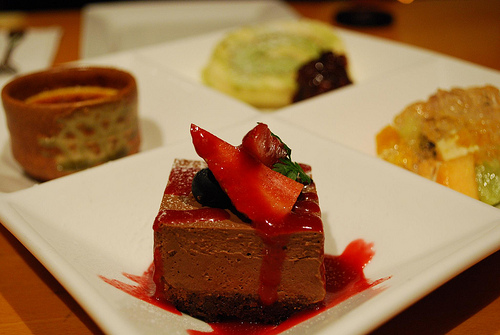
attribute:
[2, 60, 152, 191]
bowl — round, brown, small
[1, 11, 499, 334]
plate — white, square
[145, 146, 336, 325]
pastry — chocolate, square, sliced, brown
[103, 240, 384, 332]
sauce — red, drizzled, strawberry, fruity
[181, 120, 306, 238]
strawberry — slice, red, sliced, wedged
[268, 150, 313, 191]
leaf — green, sprig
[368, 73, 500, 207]
pastry — fruit, peaches, kiwi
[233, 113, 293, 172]
strawberry — sliced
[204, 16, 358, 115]
brulee — small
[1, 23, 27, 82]
fork — dessert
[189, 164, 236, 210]
blueberry — small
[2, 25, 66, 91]
napkin — paper